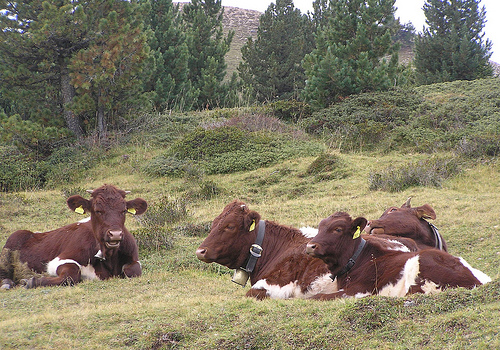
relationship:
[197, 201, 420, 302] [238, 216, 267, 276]
cow has collar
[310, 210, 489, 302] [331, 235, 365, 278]
cow has collar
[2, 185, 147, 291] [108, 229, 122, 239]
cow has nose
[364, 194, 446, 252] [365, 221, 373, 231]
cow has nose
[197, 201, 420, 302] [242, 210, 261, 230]
cow has ear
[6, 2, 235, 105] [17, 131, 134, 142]
trees have stem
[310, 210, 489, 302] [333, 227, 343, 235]
cow has eye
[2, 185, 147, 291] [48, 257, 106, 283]
cow has hair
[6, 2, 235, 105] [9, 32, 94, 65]
trees have branches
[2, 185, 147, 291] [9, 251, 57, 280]
cow has stomach